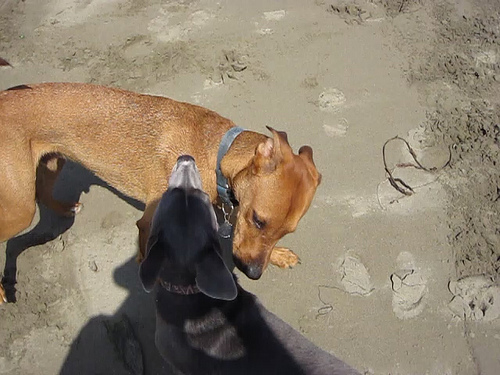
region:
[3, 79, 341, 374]
the dogs standing on the beach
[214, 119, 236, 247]
the blue collar on the brown dog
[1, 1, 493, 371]
the beach the dogs are standing on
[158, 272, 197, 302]
the black collar on the black dog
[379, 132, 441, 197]
a branch on the ground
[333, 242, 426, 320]
footprints on the sand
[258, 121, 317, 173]
the ears of the brown dog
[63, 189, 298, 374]
the shadow of a person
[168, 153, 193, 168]
the nose of the black dog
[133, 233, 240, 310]
the ears on the black dog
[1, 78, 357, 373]
Two dogs are playing together.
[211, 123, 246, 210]
The dog has a black collar.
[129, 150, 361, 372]
The dog is black.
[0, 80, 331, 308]
The dog is brown.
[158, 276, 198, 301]
The dog has multi color collar.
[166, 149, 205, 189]
The dog has a white snout.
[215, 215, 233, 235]
A small tag on the dog's collar.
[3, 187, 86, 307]
The brown dog casts a leg shadow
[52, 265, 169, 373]
The black dog casts a head shadow.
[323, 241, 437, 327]
Foot prints in the dirt.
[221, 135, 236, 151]
the grey collar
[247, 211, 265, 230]
dogs eye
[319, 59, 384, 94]
the sand on the ground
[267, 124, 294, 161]
the dogs ear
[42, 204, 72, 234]
a shadow on the ground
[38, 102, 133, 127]
the dogs fur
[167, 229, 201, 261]
a shadow on the dog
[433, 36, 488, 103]
the mud is grey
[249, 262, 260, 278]
the dogs nose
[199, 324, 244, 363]
the dog is grey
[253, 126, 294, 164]
ear of a brown dog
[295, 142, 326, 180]
ear of a brown dog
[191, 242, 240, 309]
ear of a black dog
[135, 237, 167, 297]
ear of a black dog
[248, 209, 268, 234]
eye of a brown dog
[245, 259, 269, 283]
nose of a brown dog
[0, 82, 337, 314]
brown dog wearing a grey collar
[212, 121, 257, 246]
grey collar with a silver tag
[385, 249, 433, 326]
foot step in the sand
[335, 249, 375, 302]
foot step in the sand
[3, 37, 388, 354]
two dogs smelling each other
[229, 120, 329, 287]
the head of a dog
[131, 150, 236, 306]
the head of a dog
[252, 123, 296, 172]
the ear of a dog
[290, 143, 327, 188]
the ear of a dog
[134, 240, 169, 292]
the ear of a dog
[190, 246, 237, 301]
the ear of a dog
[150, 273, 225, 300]
the collar of a dog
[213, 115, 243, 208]
the collar of a dog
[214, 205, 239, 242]
the tag of a dog